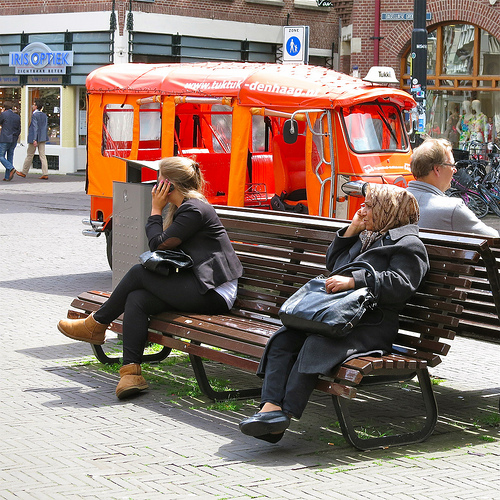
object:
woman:
[56, 156, 244, 399]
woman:
[237, 181, 429, 445]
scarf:
[367, 182, 419, 230]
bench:
[66, 203, 485, 448]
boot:
[57, 313, 110, 345]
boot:
[113, 361, 149, 398]